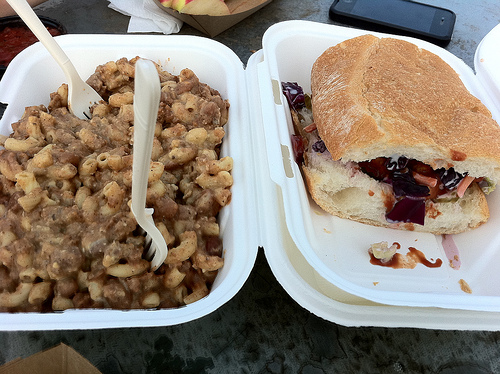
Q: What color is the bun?
A: Brown.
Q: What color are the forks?
A: White.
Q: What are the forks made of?
A: Plastic.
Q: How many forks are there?
A: Two.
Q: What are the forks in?
A: Macaroni.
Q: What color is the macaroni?
A: Yellow.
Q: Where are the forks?
A: In the macaroni.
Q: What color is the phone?
A: Black.